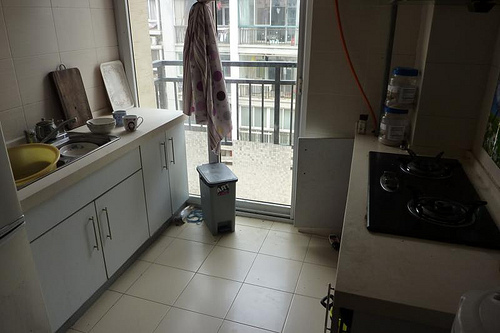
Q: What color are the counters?
A: White.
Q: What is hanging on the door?
A: A towel.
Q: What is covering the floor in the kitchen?
A: Tile.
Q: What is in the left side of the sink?
A: A bowl.